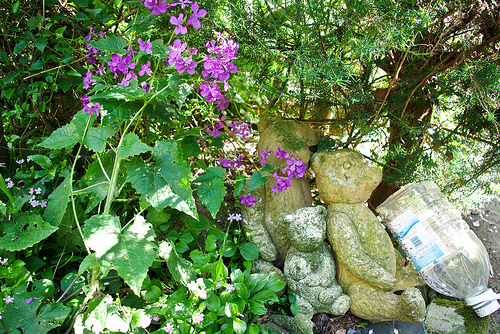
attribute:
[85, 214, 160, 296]
leaf — large, green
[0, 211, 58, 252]
leaf — large, green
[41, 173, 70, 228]
leaf — large, green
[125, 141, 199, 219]
leaf — large, green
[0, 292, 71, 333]
leaf — large, green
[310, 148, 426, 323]
bear — tan, stone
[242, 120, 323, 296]
bear — tan, stone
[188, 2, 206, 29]
flower — purple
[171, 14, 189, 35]
flower — purple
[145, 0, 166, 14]
flower — purple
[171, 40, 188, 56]
flower — purple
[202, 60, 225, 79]
flower — purple